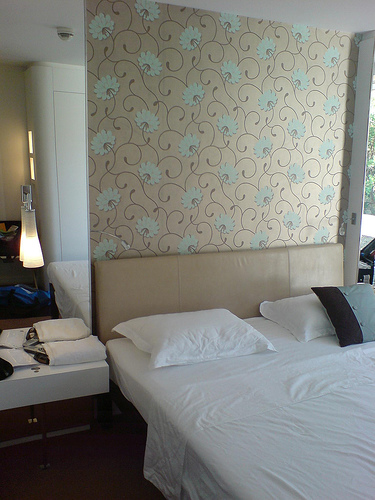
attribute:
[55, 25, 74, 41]
detector — reflection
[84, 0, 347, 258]
wall — blue , grey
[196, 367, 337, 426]
sheets — white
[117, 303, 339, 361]
pillows — white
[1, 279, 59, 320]
bag — blue 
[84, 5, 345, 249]
wallpaper — floral , blue , Brown 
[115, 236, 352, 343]
head — dark grey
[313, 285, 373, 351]
accent pillow — blue, black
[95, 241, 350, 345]
headboard — beige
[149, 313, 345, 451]
bed — white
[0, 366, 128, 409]
table — white 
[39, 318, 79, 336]
towel — white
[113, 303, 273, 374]
pillow — white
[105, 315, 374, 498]
sheet — white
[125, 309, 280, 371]
pillow — white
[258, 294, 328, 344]
pillow — white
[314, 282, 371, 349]
pillow — white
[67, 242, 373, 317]
board — Brown 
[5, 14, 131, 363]
mirror — long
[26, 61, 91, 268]
cabinet — white